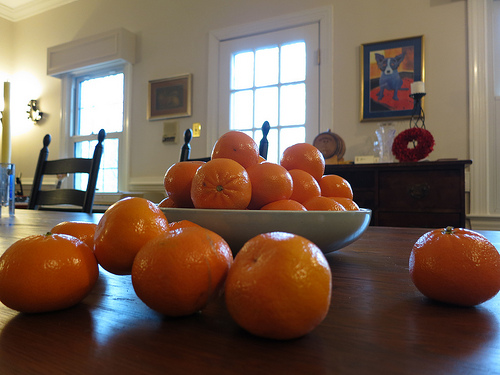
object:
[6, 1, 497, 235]
wall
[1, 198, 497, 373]
table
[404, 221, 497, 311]
orange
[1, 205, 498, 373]
dining table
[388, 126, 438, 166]
flower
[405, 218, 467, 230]
ground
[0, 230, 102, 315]
orange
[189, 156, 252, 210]
orange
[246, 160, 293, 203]
orange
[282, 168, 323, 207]
orange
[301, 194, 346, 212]
orange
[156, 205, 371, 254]
bowl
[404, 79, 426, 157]
stick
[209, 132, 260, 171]
orange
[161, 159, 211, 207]
orange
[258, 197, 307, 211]
orange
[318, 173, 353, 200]
orange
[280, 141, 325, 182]
orange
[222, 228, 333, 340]
oranges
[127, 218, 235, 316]
oranges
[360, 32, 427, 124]
painting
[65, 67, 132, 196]
window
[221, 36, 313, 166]
window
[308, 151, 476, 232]
cabinet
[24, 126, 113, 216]
chair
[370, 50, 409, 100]
dog